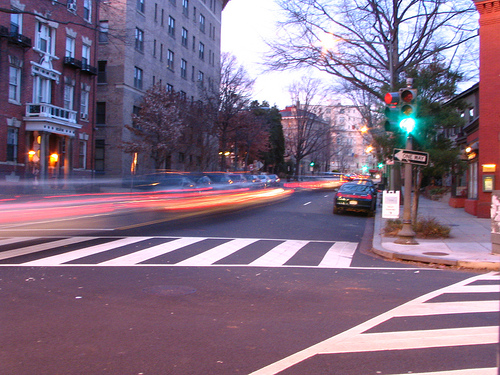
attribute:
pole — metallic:
[366, 86, 438, 246]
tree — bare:
[257, 0, 480, 202]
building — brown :
[93, 1, 226, 176]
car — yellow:
[331, 177, 383, 216]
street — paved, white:
[3, 161, 473, 373]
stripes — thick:
[6, 238, 387, 280]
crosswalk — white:
[7, 222, 499, 274]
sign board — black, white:
[383, 143, 430, 171]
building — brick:
[12, 20, 109, 197]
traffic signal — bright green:
[391, 85, 425, 141]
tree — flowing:
[122, 82, 189, 171]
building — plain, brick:
[107, 0, 222, 96]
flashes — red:
[0, 160, 340, 219]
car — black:
[334, 180, 376, 215]